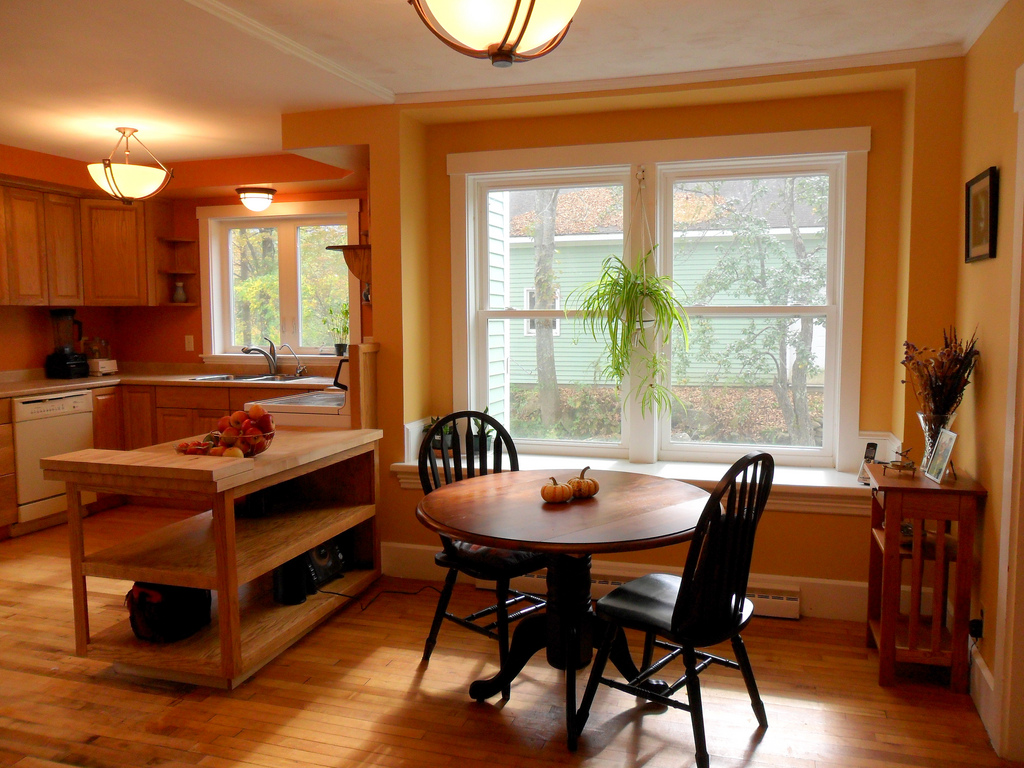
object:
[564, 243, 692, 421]
leaves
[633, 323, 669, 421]
leaves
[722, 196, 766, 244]
leaves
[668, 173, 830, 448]
tree